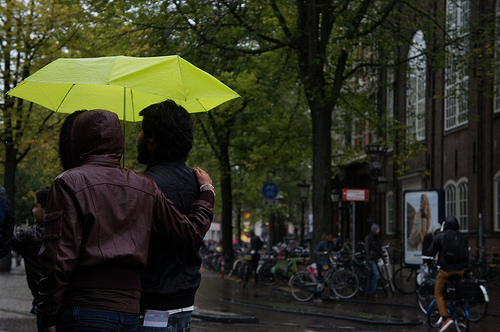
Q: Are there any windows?
A: Yes, there are windows.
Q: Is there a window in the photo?
A: Yes, there are windows.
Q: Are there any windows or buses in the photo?
A: Yes, there are windows.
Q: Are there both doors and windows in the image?
A: No, there are windows but no doors.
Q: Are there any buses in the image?
A: No, there are no buses.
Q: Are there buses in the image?
A: No, there are no buses.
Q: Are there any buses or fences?
A: No, there are no buses or fences.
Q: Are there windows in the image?
A: Yes, there are windows.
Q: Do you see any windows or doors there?
A: Yes, there are windows.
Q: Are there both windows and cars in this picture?
A: No, there are windows but no cars.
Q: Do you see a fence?
A: No, there are no fences.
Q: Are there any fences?
A: No, there are no fences.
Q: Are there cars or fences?
A: No, there are no fences or cars.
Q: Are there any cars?
A: No, there are no cars.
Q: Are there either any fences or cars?
A: No, there are no cars or fences.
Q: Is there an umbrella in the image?
A: Yes, there is an umbrella.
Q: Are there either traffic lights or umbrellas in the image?
A: Yes, there is an umbrella.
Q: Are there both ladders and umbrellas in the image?
A: No, there is an umbrella but no ladders.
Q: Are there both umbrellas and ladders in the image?
A: No, there is an umbrella but no ladders.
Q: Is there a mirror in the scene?
A: No, there are no mirrors.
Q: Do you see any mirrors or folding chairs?
A: No, there are no mirrors or folding chairs.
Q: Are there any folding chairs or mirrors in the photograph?
A: No, there are no mirrors or folding chairs.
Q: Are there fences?
A: No, there are no fences.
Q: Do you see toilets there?
A: No, there are no toilets.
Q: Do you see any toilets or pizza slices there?
A: No, there are no toilets or pizza slices.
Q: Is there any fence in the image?
A: No, there are no fences.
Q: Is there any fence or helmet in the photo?
A: No, there are no fences or helmets.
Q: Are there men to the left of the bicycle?
A: Yes, there is a man to the left of the bicycle.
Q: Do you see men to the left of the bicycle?
A: Yes, there is a man to the left of the bicycle.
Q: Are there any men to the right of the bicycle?
A: No, the man is to the left of the bicycle.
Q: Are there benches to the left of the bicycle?
A: No, there is a man to the left of the bicycle.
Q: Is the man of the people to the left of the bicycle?
A: Yes, the man is to the left of the bicycle.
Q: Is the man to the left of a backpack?
A: No, the man is to the left of the bicycle.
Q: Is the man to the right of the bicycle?
A: No, the man is to the left of the bicycle.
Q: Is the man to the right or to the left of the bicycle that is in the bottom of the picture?
A: The man is to the left of the bicycle.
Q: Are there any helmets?
A: No, there are no helmets.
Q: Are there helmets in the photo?
A: No, there are no helmets.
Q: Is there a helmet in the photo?
A: No, there are no helmets.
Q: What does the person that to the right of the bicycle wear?
A: The person wears trousers.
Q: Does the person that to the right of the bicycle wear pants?
A: Yes, the person wears pants.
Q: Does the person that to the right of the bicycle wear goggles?
A: No, the person wears pants.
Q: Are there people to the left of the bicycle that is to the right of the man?
A: No, the person is to the right of the bicycle.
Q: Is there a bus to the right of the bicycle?
A: No, there is a person to the right of the bicycle.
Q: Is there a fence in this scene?
A: No, there are no fences.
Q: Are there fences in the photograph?
A: No, there are no fences.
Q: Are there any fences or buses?
A: No, there are no fences or buses.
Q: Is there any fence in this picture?
A: No, there are no fences.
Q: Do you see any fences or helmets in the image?
A: No, there are no fences or helmets.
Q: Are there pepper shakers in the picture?
A: No, there are no pepper shakers.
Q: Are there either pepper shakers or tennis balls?
A: No, there are no pepper shakers or tennis balls.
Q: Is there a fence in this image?
A: No, there are no fences.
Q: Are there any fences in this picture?
A: No, there are no fences.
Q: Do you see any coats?
A: Yes, there is a coat.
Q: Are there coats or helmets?
A: Yes, there is a coat.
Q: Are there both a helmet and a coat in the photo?
A: No, there is a coat but no helmets.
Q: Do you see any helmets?
A: No, there are no helmets.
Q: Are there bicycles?
A: Yes, there is a bicycle.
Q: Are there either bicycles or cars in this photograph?
A: Yes, there is a bicycle.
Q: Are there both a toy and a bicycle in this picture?
A: No, there is a bicycle but no toys.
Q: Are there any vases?
A: No, there are no vases.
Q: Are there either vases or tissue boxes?
A: No, there are no vases or tissue boxes.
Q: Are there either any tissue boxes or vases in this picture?
A: No, there are no vases or tissue boxes.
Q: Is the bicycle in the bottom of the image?
A: Yes, the bicycle is in the bottom of the image.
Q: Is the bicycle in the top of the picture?
A: No, the bicycle is in the bottom of the image.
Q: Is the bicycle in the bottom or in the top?
A: The bicycle is in the bottom of the image.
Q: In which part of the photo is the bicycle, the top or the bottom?
A: The bicycle is in the bottom of the image.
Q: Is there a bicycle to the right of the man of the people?
A: Yes, there is a bicycle to the right of the man.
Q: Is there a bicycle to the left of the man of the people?
A: No, the bicycle is to the right of the man.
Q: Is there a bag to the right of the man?
A: No, there is a bicycle to the right of the man.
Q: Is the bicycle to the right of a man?
A: Yes, the bicycle is to the right of a man.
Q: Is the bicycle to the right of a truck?
A: No, the bicycle is to the right of a man.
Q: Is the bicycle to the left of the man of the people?
A: No, the bicycle is to the right of the man.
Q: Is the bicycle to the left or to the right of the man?
A: The bicycle is to the right of the man.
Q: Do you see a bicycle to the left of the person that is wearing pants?
A: Yes, there is a bicycle to the left of the person.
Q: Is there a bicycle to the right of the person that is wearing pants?
A: No, the bicycle is to the left of the person.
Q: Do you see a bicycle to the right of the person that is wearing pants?
A: No, the bicycle is to the left of the person.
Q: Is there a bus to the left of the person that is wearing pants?
A: No, there is a bicycle to the left of the person.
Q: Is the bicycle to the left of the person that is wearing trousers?
A: Yes, the bicycle is to the left of the person.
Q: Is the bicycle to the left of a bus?
A: No, the bicycle is to the left of the person.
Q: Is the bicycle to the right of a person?
A: No, the bicycle is to the left of a person.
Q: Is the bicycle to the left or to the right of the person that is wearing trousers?
A: The bicycle is to the left of the person.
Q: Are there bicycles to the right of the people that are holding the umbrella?
A: Yes, there is a bicycle to the right of the people.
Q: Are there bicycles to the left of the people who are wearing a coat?
A: No, the bicycle is to the right of the people.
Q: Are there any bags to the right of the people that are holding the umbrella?
A: No, there is a bicycle to the right of the people.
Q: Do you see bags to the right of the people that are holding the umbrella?
A: No, there is a bicycle to the right of the people.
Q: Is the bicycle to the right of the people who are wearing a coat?
A: Yes, the bicycle is to the right of the people.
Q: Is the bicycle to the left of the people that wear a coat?
A: No, the bicycle is to the right of the people.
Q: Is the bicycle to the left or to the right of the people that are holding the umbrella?
A: The bicycle is to the right of the people.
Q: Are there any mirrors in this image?
A: No, there are no mirrors.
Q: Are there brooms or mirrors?
A: No, there are no mirrors or brooms.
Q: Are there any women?
A: Yes, there is a woman.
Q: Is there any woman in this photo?
A: Yes, there is a woman.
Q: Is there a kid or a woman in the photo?
A: Yes, there is a woman.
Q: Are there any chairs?
A: No, there are no chairs.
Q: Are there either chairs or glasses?
A: No, there are no chairs or glasses.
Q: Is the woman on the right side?
A: Yes, the woman is on the right of the image.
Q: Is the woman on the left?
A: No, the woman is on the right of the image.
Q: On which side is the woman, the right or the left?
A: The woman is on the right of the image.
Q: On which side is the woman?
A: The woman is on the right of the image.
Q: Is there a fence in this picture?
A: No, there are no fences.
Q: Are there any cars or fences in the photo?
A: No, there are no fences or cars.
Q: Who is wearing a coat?
A: The people are wearing a coat.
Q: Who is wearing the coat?
A: The people are wearing a coat.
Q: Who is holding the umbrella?
A: The people are holding the umbrella.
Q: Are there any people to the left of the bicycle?
A: Yes, there are people to the left of the bicycle.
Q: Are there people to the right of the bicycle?
A: No, the people are to the left of the bicycle.